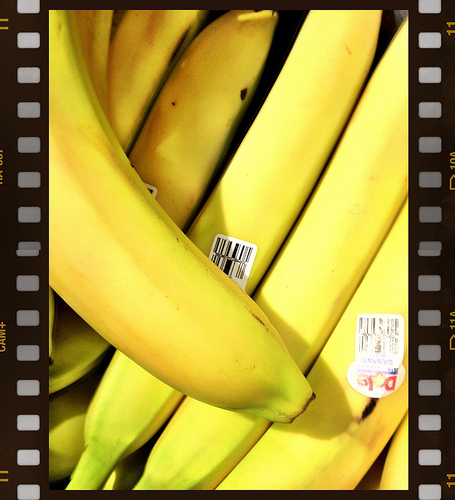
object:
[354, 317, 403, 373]
code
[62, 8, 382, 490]
banana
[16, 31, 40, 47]
rectangle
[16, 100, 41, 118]
rectangle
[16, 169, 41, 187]
rectangle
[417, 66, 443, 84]
rectangle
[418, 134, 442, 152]
rectangle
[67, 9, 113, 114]
banana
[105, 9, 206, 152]
banana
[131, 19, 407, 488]
banana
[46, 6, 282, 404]
banana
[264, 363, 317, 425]
end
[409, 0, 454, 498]
film edging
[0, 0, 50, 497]
film edging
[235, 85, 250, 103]
brown spot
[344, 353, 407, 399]
dole sticker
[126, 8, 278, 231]
banana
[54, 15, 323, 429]
banana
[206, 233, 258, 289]
sticker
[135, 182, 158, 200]
sticker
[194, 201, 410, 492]
banana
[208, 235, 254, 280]
code